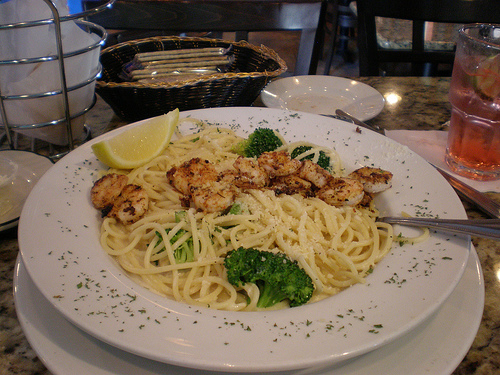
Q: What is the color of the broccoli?
A: Is green.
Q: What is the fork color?
A: Is silver.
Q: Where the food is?
A: In a plate.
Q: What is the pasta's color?
A: Is yellow.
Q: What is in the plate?
A: The food.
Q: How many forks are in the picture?
A: One.